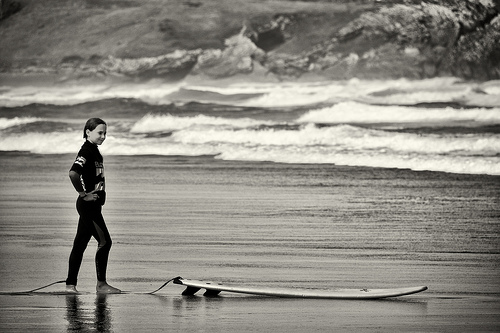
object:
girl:
[61, 110, 125, 301]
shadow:
[57, 289, 118, 333]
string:
[0, 272, 71, 301]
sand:
[228, 251, 255, 265]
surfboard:
[167, 267, 441, 311]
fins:
[177, 283, 204, 299]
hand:
[77, 191, 100, 203]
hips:
[73, 194, 103, 216]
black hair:
[89, 119, 96, 124]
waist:
[78, 193, 87, 198]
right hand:
[62, 149, 102, 203]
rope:
[90, 273, 188, 299]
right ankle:
[95, 283, 105, 290]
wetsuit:
[59, 143, 119, 291]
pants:
[59, 194, 123, 297]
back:
[0, 273, 182, 301]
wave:
[0, 0, 500, 132]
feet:
[88, 275, 126, 298]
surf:
[1, 58, 500, 173]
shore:
[0, 144, 500, 330]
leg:
[61, 214, 91, 296]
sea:
[0, 1, 498, 174]